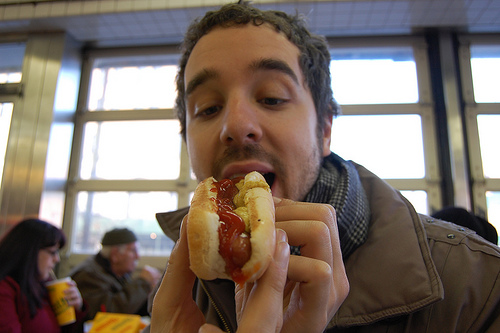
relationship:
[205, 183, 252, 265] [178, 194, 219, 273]
hotdog in bun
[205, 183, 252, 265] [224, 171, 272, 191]
hotdog to eat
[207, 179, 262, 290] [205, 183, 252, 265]
ketchup on hotdog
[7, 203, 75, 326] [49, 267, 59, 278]
woman using straw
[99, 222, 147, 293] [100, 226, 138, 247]
man with cap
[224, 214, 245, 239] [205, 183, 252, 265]
ketchup on hotdog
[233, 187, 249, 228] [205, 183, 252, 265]
mustard on hotdog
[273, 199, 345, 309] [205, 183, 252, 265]
hands holding hotdog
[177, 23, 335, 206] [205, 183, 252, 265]
man biting hotdog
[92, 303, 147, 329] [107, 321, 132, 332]
box with writing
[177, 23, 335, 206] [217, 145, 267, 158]
man has mustache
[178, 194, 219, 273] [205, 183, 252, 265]
bun filled with hotdog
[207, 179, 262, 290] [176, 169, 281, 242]
ketchup on food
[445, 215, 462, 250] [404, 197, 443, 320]
rivets on coat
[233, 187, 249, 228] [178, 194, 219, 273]
mustard on bun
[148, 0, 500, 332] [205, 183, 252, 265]
man holding hotdog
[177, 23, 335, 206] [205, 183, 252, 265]
man enjoying hotdog